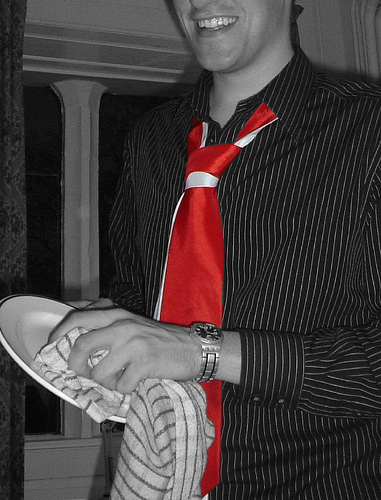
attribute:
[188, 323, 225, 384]
watch — silver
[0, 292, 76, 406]
plate — white, round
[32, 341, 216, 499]
rag — white, stripped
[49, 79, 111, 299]
post — white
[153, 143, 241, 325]
tie — red, thick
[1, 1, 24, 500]
curtain — long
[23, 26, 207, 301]
window — dark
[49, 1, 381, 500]
man — smiling, drying, ring-less, photographed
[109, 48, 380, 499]
shirt — striped, stripped, fancy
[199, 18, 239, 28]
teeth — white